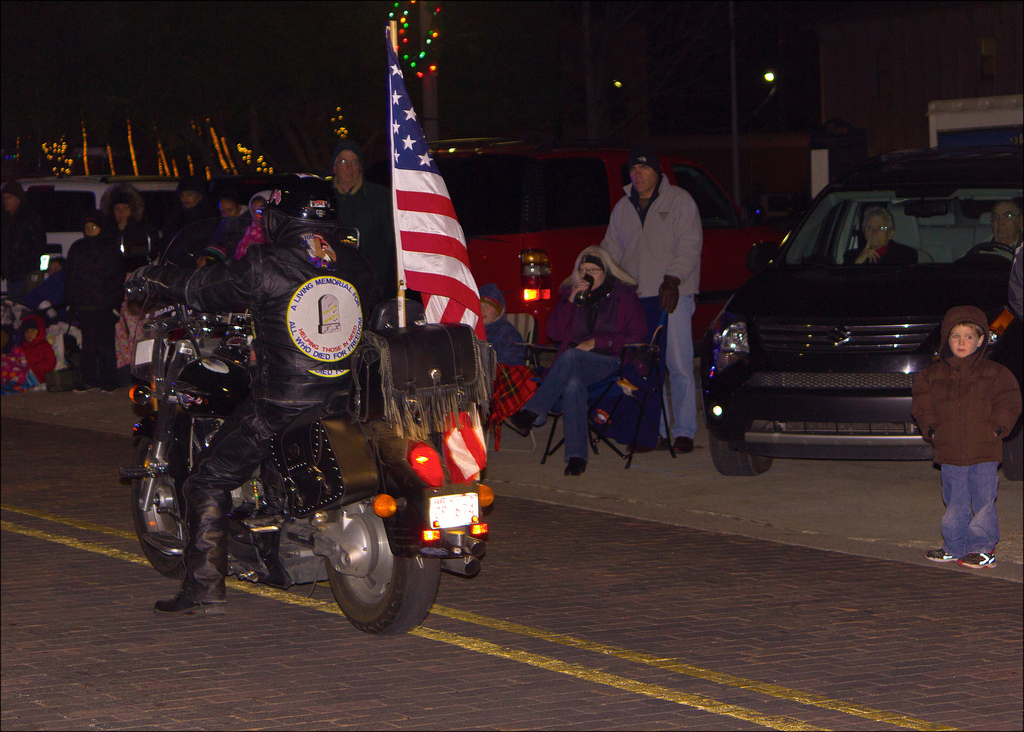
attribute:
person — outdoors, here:
[581, 134, 723, 356]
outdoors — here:
[54, 46, 973, 552]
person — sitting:
[574, 247, 687, 404]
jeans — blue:
[529, 345, 645, 452]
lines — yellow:
[436, 602, 752, 710]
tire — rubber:
[302, 539, 482, 651]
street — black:
[520, 518, 751, 624]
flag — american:
[386, 55, 509, 325]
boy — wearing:
[884, 270, 1013, 530]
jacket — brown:
[907, 336, 1012, 457]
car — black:
[738, 188, 955, 477]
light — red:
[371, 431, 447, 499]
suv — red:
[441, 156, 630, 301]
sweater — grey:
[588, 105, 805, 391]